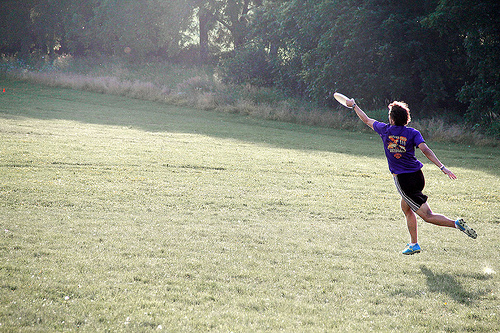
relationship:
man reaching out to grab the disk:
[346, 98, 478, 256] [329, 86, 351, 106]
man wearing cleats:
[342, 88, 477, 258] [457, 213, 478, 239]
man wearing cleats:
[342, 88, 477, 258] [400, 241, 422, 256]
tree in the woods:
[184, 0, 252, 74] [26, 3, 474, 128]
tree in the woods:
[256, 6, 289, 78] [26, 3, 474, 128]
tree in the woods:
[304, 12, 368, 95] [20, 9, 480, 115]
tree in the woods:
[410, 13, 484, 106] [26, 3, 474, 128]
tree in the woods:
[410, 13, 484, 106] [20, 9, 480, 115]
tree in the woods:
[119, 11, 164, 63] [26, 3, 474, 128]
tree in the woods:
[44, 9, 82, 67] [20, 9, 480, 115]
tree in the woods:
[10, 6, 50, 55] [26, 3, 474, 128]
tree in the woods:
[131, 19, 303, 76] [12, 9, 484, 129]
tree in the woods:
[410, 13, 484, 106] [7, 6, 477, 142]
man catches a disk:
[342, 88, 477, 258] [333, 92, 353, 108]